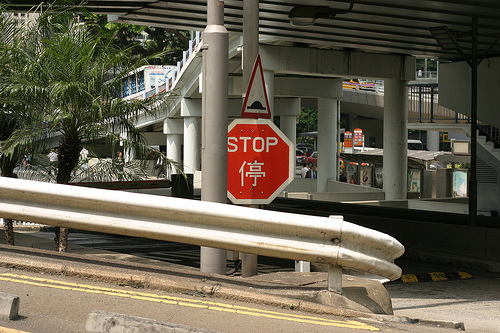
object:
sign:
[228, 119, 296, 206]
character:
[239, 160, 266, 186]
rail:
[1, 175, 405, 295]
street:
[0, 222, 497, 333]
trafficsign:
[242, 54, 272, 119]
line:
[1, 270, 374, 332]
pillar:
[382, 78, 407, 202]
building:
[1, 10, 40, 40]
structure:
[336, 147, 456, 197]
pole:
[242, 0, 260, 278]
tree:
[2, 4, 172, 249]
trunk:
[56, 226, 70, 253]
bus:
[99, 64, 176, 101]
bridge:
[13, 38, 203, 181]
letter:
[227, 137, 278, 153]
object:
[247, 100, 266, 110]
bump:
[402, 271, 474, 283]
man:
[305, 165, 318, 179]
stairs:
[476, 125, 500, 162]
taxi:
[342, 79, 375, 93]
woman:
[301, 162, 310, 178]